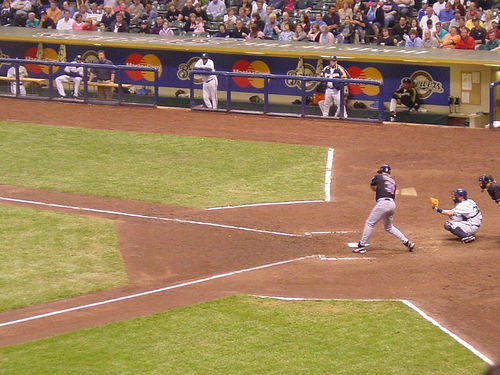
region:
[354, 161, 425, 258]
batter at first base swinging bat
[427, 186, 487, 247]
catcher behind batter ready to catch a foul ball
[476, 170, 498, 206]
referee behind catcher watching the game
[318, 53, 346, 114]
player standing behind railing watching game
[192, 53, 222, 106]
player standing behind railing watching game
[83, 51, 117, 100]
man not in uniform standing behind railing watching game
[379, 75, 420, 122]
player in uniform sitting on bench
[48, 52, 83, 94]
player in uniform sitting on bench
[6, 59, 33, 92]
player sitting on bench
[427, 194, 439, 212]
catchers mitt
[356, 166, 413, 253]
player swings bat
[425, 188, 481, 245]
player gets ready to catch ball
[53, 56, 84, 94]
player watches the game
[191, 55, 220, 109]
player watches the game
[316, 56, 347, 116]
player watches the game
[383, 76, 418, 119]
player watches the game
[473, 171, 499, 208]
umpire gets ready to make a call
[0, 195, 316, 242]
line is used to mark the playing field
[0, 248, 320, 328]
line is used to mark the playing field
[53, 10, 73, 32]
human watches the game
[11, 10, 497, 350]
a baseball game is taking place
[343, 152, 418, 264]
this player is up at bat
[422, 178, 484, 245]
this player is the catcher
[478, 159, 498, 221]
the umpire can be seen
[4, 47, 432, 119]
these players are in the dugout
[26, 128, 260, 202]
this area of the playing field is green grass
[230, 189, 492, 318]
this area of the field is dirt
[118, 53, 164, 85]
the MasterCard logo is on the dugout wall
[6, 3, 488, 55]
the crowd is watching the game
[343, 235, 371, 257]
home plate is under the batter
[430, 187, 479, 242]
the baseball player at the game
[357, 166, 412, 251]
the baseball player at the game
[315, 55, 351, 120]
the baseball player at the game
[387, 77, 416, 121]
the baseball player at the game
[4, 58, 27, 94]
the baseball player at the game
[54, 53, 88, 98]
the baseball player at the game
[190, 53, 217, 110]
the baseball player at the game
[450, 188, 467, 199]
the purple hat on the player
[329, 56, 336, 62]
the purple hat on the player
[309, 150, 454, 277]
person hitting a baseball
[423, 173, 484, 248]
a baseball catcher on a field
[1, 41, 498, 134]
baseball players watching from the dugout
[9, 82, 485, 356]
a baseball field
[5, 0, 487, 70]
a crowd in the stands watching a baseball game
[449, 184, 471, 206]
a man wearing a helmet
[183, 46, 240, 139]
a baseball player leaning on a rail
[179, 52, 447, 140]
a railing alongside a field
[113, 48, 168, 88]
an advertisement for mastercard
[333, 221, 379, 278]
home plate on a baseball field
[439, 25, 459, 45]
a person is sitting down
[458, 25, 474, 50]
a person is sitting down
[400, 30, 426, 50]
a person is sitting down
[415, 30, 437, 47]
a person is sitting down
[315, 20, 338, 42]
a person is sitting down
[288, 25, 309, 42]
a person is sitting down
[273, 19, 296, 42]
a person is sitting down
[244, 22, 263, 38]
a person is sitting down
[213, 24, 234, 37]
a person is sitting down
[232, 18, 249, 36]
a person is sitting down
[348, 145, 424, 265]
man swinging a bat